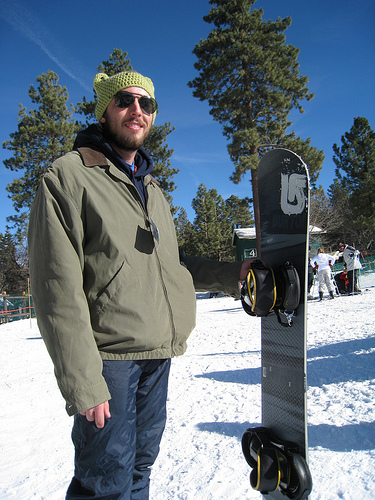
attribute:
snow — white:
[0, 270, 374, 499]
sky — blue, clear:
[0, 0, 375, 268]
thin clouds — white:
[2, 2, 374, 265]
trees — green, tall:
[0, 0, 374, 301]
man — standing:
[28, 71, 198, 499]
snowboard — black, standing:
[239, 147, 312, 499]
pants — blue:
[67, 359, 172, 499]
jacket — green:
[28, 145, 197, 416]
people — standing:
[30, 72, 362, 499]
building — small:
[230, 224, 328, 264]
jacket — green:
[28, 146, 243, 416]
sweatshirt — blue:
[72, 122, 154, 211]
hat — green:
[94, 72, 157, 127]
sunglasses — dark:
[113, 89, 158, 114]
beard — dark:
[102, 107, 152, 151]